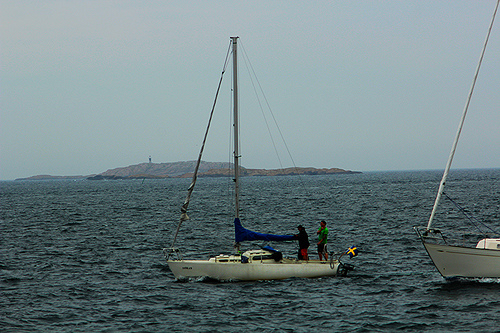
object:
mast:
[229, 30, 242, 252]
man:
[314, 217, 331, 262]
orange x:
[346, 245, 358, 256]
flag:
[345, 242, 361, 258]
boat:
[421, 5, 498, 287]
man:
[290, 218, 312, 268]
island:
[83, 160, 363, 181]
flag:
[229, 215, 293, 247]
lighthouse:
[147, 155, 154, 162]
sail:
[234, 217, 299, 242]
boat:
[156, 33, 363, 285]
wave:
[172, 275, 227, 289]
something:
[292, 241, 312, 264]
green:
[314, 226, 334, 246]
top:
[221, 30, 243, 50]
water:
[0, 173, 500, 333]